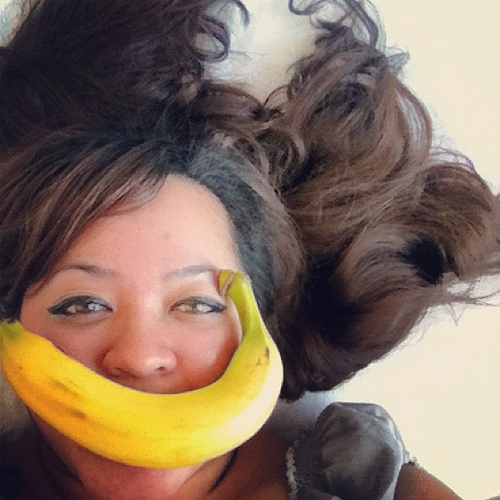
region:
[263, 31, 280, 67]
part of a wall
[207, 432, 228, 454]
part of a banana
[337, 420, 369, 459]
part of a cloth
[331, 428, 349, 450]
part of a cloth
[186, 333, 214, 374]
part of a cheek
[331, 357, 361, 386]
part of a haior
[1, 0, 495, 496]
a woman lying on a white surface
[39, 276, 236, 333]
woman eyes are brown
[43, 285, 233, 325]
eyes have makeup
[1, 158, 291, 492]
a banana over a face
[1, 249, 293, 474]
banana has a C shape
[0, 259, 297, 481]
a ripe banana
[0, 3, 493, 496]
hair of woman is brown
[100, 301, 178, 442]
nose above a banana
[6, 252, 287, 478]
banana is color yellow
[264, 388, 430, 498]
sleeve of a blouse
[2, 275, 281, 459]
banana on woman's face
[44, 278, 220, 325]
brown eyes of woman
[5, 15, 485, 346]
brown hair of woman with brown eyes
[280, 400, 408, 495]
sleeve of woman's blouse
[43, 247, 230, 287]
brown eyebrows of woman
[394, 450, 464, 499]
arm of woman with banana on her face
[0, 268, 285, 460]
yellow peel of banana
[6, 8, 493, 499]
white sheets woman is laying on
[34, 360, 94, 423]
brown spots on yellow banana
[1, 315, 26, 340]
green end of yellow banana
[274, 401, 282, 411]
part of a banana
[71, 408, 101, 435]
side of a banana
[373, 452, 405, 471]
part of a clothe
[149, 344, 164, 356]
part of a nose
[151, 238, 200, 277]
head of a woman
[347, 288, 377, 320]
hair of a woman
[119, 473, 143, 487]
chin of a woman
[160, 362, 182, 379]
nose of a woman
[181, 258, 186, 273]
eye brows of a lady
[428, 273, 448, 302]
tip of an hair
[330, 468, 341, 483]
part of a clothe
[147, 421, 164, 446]
side of a banana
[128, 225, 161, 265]
forehead of a lady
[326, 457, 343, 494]
part of a dress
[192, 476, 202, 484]
neck of a woman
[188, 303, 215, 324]
eye of a woman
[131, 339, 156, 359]
nose of a woman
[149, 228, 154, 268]
part of a forehead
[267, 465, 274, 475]
part of a shoulder